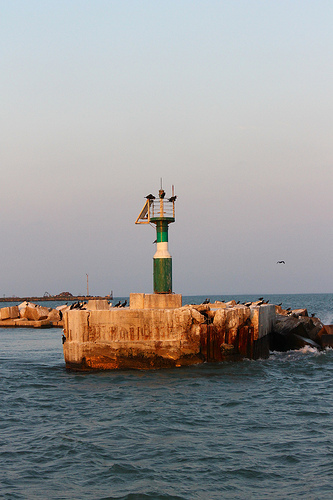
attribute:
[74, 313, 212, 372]
rock — worn, discolored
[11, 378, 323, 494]
water — choppy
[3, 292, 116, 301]
ship — commercial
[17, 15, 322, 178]
sky — blue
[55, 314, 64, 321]
bird — black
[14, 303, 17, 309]
bird — black